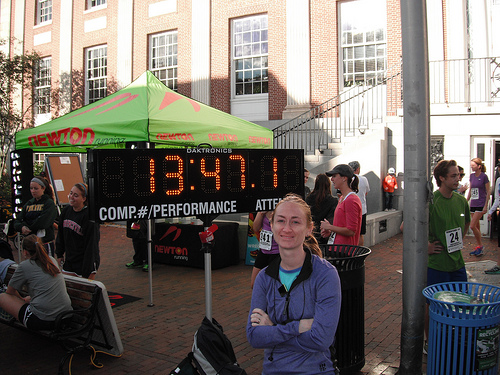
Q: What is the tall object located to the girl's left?
A: A long grey pole.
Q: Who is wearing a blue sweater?
A: Lady with her arms crossed.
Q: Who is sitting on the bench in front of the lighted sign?
A: Lady with a ponytail.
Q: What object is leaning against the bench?
A: A table.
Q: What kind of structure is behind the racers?
A: Brick building with windows.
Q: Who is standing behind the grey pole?
A: A man in a green shirt.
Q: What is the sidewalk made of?
A: Bricks.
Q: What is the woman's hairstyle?
A: Ponytail.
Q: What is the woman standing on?
A: Bricks.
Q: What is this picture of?
A: Runners gathering for a race.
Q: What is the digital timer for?
A: To time the runners.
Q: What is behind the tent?
A: A building.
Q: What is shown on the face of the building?
A: Windows.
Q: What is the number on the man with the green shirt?
A: 24.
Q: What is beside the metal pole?
A: A blue trashcan.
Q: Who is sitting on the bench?
A: A girl.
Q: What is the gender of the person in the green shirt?
A: Male.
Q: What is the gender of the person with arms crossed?
A: Female.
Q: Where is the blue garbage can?
A: Near the silver pole.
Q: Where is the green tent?
A: In front of the building.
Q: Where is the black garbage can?
A: Behind the girl in the purple shirt.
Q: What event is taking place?
A: A race.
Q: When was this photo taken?
A: During the day.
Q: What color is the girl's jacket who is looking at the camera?
A: Blue.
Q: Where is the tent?
A: Behind the electronic clock.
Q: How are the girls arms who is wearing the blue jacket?
A: Crossed in front of her.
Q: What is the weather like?
A: Sunny.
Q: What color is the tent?
A: Green.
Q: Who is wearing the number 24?
A: Guy in green shirt.